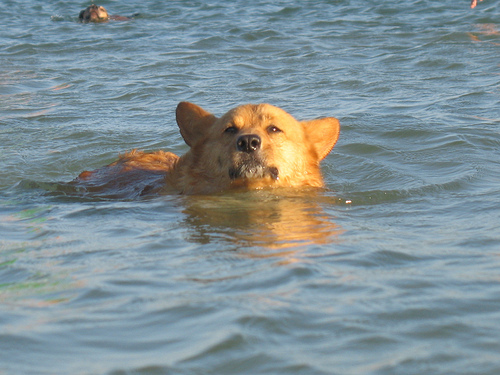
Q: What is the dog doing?
A: Swimming.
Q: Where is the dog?
A: In the water.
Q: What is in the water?
A: The dog.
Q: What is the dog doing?
A: Swimming.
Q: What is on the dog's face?
A: A nose.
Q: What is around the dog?
A: Ripples.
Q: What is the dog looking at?
A: A photographer.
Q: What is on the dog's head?
A: Big ears.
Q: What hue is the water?
A: Blue green.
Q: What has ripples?
A: The water.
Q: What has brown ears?
A: The dog.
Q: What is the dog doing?
A: Swimming.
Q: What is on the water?
A: The dog's reflection.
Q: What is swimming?
A: A dog.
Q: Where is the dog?
A: In the water.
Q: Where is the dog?
A: In the water.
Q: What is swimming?
A: The dog.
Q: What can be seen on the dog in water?
A: His head.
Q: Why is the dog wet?
A: He is in the water.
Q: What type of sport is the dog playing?
A: Swimming.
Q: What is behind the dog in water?
A: Another dog.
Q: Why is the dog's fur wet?
A: It is swimming in water.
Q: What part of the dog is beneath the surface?
A: Its body.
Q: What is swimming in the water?
A: A dog.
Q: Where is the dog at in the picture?
A: The water.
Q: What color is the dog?
A: Blonde.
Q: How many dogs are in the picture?
A: One.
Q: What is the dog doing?
A: Swimming.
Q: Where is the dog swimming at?
A: In the water.